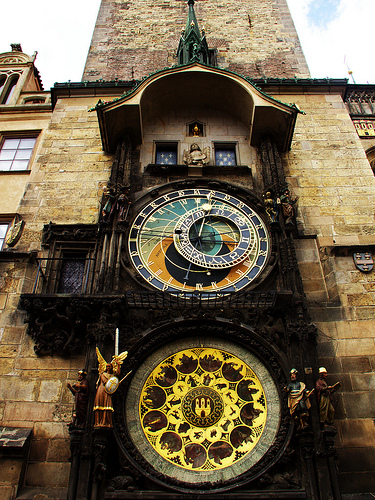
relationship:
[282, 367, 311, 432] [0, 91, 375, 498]
statue on castel`s wall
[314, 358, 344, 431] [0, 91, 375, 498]
statue on castel`s wall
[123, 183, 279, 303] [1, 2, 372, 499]
clock on building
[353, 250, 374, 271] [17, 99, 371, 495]
shield on wall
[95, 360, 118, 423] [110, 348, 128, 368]
person has wing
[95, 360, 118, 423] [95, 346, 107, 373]
person has wing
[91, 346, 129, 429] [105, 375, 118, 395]
person holding shield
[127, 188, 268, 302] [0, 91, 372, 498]
clock on castel`s wall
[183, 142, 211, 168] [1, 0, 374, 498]
man drawn on building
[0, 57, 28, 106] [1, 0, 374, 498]
door on building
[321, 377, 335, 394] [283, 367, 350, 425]
hand on person